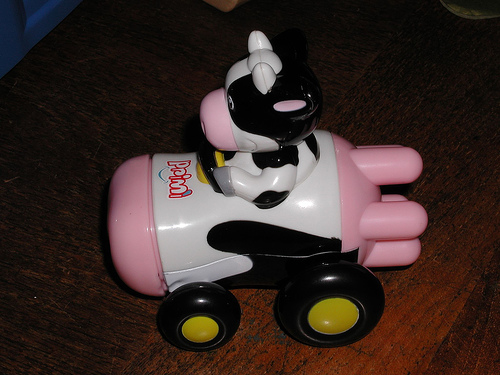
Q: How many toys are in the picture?
A: One.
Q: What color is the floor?
A: Brown.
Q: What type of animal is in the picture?
A: A cow.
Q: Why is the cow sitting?
A: He is driving the car.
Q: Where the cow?
A: Sitting in the car.